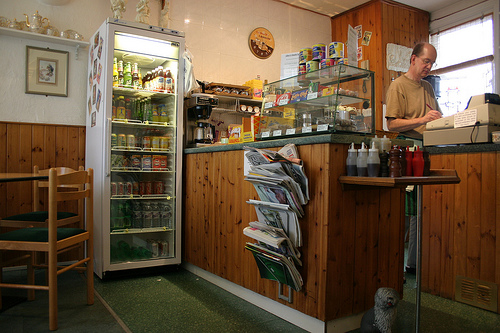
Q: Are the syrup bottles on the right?
A: Yes, the bottles are on the right of the image.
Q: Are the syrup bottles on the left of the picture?
A: No, the bottles are on the right of the image.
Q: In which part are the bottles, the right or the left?
A: The bottles are on the right of the image.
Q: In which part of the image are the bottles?
A: The bottles are on the right of the image.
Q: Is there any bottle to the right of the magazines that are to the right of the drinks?
A: Yes, there are bottles to the right of the magazines.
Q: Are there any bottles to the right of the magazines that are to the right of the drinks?
A: Yes, there are bottles to the right of the magazines.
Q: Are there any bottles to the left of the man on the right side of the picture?
A: Yes, there are bottles to the left of the man.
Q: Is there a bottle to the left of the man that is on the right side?
A: Yes, there are bottles to the left of the man.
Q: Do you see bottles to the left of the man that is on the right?
A: Yes, there are bottles to the left of the man.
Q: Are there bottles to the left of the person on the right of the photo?
A: Yes, there are bottles to the left of the man.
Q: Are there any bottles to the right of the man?
A: No, the bottles are to the left of the man.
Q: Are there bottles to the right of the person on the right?
A: No, the bottles are to the left of the man.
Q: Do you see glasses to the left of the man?
A: No, there are bottles to the left of the man.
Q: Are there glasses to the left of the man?
A: No, there are bottles to the left of the man.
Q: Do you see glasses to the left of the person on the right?
A: No, there are bottles to the left of the man.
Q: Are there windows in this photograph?
A: Yes, there is a window.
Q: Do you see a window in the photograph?
A: Yes, there is a window.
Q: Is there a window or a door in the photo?
A: Yes, there is a window.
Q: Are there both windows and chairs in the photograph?
A: Yes, there are both a window and a chair.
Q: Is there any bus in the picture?
A: No, there are no buses.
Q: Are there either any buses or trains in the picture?
A: No, there are no buses or trains.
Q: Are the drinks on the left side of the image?
A: Yes, the drinks are on the left of the image.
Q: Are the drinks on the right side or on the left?
A: The drinks are on the left of the image.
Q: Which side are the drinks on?
A: The drinks are on the left of the image.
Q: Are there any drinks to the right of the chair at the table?
A: Yes, there are drinks to the right of the chair.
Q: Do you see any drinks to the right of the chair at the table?
A: Yes, there are drinks to the right of the chair.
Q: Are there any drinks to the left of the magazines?
A: Yes, there are drinks to the left of the magazines.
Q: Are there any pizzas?
A: No, there are no pizzas.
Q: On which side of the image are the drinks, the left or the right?
A: The drinks are on the left of the image.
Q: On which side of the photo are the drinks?
A: The drinks are on the left of the image.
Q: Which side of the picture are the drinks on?
A: The drinks are on the left of the image.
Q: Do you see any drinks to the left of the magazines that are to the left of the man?
A: Yes, there are drinks to the left of the magazines.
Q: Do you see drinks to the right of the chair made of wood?
A: Yes, there are drinks to the right of the chair.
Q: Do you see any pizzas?
A: No, there are no pizzas.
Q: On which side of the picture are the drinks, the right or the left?
A: The drinks are on the left of the image.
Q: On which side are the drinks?
A: The drinks are on the left of the image.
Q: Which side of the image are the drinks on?
A: The drinks are on the left of the image.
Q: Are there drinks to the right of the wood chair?
A: Yes, there are drinks to the right of the chair.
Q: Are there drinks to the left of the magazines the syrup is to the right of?
A: Yes, there are drinks to the left of the magazines.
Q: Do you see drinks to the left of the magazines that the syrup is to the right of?
A: Yes, there are drinks to the left of the magazines.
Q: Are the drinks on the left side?
A: Yes, the drinks are on the left of the image.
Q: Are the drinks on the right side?
A: No, the drinks are on the left of the image.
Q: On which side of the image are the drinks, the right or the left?
A: The drinks are on the left of the image.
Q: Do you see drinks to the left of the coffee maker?
A: Yes, there are drinks to the left of the coffee maker.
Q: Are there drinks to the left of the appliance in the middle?
A: Yes, there are drinks to the left of the coffee maker.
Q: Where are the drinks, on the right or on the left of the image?
A: The drinks are on the left of the image.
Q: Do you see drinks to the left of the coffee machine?
A: Yes, there are drinks to the left of the coffee machine.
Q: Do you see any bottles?
A: Yes, there is a bottle.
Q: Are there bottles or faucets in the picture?
A: Yes, there is a bottle.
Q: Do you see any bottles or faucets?
A: Yes, there is a bottle.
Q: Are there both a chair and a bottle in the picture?
A: Yes, there are both a bottle and a chair.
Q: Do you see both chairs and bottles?
A: Yes, there are both a bottle and a chair.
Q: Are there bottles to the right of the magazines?
A: Yes, there is a bottle to the right of the magazines.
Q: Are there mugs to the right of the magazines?
A: No, there is a bottle to the right of the magazines.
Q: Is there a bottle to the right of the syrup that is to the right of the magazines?
A: Yes, there is a bottle to the right of the syrup.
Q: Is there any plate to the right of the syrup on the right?
A: No, there is a bottle to the right of the syrup.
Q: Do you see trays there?
A: No, there are no trays.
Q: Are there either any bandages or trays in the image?
A: No, there are no trays or bandages.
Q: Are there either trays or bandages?
A: No, there are no trays or bandages.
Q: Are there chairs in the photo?
A: Yes, there is a chair.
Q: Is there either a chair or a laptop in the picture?
A: Yes, there is a chair.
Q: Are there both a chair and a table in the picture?
A: Yes, there are both a chair and a table.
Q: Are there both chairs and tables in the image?
A: Yes, there are both a chair and a table.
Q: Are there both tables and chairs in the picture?
A: Yes, there are both a chair and a table.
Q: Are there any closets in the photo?
A: No, there are no closets.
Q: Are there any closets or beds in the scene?
A: No, there are no closets or beds.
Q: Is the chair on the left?
A: Yes, the chair is on the left of the image.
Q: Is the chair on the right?
A: No, the chair is on the left of the image.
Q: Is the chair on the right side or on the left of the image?
A: The chair is on the left of the image.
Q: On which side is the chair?
A: The chair is on the left of the image.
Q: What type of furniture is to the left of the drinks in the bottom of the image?
A: The piece of furniture is a chair.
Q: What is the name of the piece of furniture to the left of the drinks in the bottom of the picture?
A: The piece of furniture is a chair.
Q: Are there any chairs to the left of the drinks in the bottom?
A: Yes, there is a chair to the left of the drinks.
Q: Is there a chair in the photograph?
A: Yes, there is a chair.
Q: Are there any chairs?
A: Yes, there is a chair.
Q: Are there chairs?
A: Yes, there is a chair.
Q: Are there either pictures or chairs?
A: Yes, there is a chair.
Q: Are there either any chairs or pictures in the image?
A: Yes, there is a chair.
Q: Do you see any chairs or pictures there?
A: Yes, there is a chair.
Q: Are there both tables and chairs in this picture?
A: Yes, there are both a chair and a table.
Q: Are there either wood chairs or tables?
A: Yes, there is a wood chair.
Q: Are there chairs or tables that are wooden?
A: Yes, the chair is wooden.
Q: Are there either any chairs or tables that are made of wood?
A: Yes, the chair is made of wood.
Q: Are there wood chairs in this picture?
A: Yes, there is a wood chair.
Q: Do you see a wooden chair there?
A: Yes, there is a wood chair.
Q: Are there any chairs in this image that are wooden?
A: Yes, there is a chair that is wooden.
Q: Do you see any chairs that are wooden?
A: Yes, there is a chair that is wooden.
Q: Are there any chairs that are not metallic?
A: Yes, there is a wooden chair.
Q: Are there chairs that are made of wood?
A: Yes, there is a chair that is made of wood.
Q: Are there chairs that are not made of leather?
A: Yes, there is a chair that is made of wood.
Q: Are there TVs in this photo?
A: No, there are no tvs.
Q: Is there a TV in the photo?
A: No, there are no televisions.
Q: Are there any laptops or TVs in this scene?
A: No, there are no TVs or laptops.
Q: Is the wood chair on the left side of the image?
A: Yes, the chair is on the left of the image.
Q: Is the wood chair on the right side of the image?
A: No, the chair is on the left of the image.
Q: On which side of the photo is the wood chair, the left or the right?
A: The chair is on the left of the image.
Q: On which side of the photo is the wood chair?
A: The chair is on the left of the image.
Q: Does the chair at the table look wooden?
A: Yes, the chair is wooden.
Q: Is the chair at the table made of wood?
A: Yes, the chair is made of wood.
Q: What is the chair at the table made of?
A: The chair is made of wood.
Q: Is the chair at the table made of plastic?
A: No, the chair is made of wood.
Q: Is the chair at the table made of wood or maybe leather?
A: The chair is made of wood.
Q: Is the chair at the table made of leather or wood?
A: The chair is made of wood.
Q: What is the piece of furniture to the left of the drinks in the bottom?
A: The piece of furniture is a chair.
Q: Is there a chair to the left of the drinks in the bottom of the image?
A: Yes, there is a chair to the left of the drinks.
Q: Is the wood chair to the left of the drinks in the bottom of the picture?
A: Yes, the chair is to the left of the drinks.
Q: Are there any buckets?
A: No, there are no buckets.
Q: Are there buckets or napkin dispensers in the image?
A: No, there are no buckets or napkin dispensers.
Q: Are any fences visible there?
A: No, there are no fences.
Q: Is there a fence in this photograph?
A: No, there are no fences.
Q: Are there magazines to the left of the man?
A: Yes, there are magazines to the left of the man.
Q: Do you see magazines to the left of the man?
A: Yes, there are magazines to the left of the man.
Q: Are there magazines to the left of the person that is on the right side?
A: Yes, there are magazines to the left of the man.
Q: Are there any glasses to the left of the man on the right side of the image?
A: No, there are magazines to the left of the man.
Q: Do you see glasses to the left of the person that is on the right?
A: No, there are magazines to the left of the man.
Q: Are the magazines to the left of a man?
A: Yes, the magazines are to the left of a man.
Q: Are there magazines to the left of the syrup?
A: Yes, there are magazines to the left of the syrup.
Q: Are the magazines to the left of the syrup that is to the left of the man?
A: Yes, the magazines are to the left of the syrup.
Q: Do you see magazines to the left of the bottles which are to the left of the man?
A: Yes, there are magazines to the left of the bottles.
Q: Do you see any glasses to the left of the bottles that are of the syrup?
A: No, there are magazines to the left of the bottles.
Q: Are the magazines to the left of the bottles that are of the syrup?
A: Yes, the magazines are to the left of the bottles.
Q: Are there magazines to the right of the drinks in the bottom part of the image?
A: Yes, there are magazines to the right of the drinks.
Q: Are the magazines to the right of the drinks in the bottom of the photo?
A: Yes, the magazines are to the right of the drinks.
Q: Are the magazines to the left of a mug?
A: No, the magazines are to the left of the bottle.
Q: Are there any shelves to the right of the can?
A: No, there are magazines to the right of the can.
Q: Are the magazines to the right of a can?
A: Yes, the magazines are to the right of a can.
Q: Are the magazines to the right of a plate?
A: No, the magazines are to the right of a can.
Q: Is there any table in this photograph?
A: Yes, there is a table.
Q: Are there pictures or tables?
A: Yes, there is a table.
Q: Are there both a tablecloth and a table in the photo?
A: No, there is a table but no tablecloths.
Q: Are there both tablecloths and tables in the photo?
A: No, there is a table but no tablecloths.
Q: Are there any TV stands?
A: No, there are no TV stands.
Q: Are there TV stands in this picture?
A: No, there are no TV stands.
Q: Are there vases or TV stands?
A: No, there are no TV stands or vases.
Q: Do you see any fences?
A: No, there are no fences.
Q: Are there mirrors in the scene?
A: No, there are no mirrors.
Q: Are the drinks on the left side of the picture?
A: Yes, the drinks are on the left of the image.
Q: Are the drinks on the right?
A: No, the drinks are on the left of the image.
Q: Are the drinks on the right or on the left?
A: The drinks are on the left of the image.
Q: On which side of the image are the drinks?
A: The drinks are on the left of the image.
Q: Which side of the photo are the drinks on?
A: The drinks are on the left of the image.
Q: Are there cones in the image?
A: No, there are no cones.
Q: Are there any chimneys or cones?
A: No, there are no cones or chimneys.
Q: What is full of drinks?
A: The cooler is full of drinks.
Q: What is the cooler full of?
A: The cooler is full of drinks.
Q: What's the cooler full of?
A: The cooler is full of drinks.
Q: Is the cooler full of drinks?
A: Yes, the cooler is full of drinks.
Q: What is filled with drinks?
A: The cooler is filled with drinks.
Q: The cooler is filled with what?
A: The cooler is filled with drinks.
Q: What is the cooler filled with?
A: The cooler is filled with drinks.